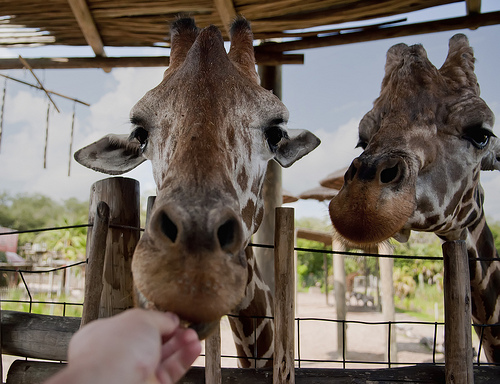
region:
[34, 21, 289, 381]
giraffe taking food from a hand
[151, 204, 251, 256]
nostrils of a giraffe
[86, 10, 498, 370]
two giraffes looking for food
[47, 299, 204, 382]
a persons hand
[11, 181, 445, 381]
fence with wooden posts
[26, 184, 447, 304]
greenery in the background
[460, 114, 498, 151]
black lashed eye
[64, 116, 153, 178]
furry little ear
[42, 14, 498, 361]
giraffes in a cage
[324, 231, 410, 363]
tall wooden posts behind the giraffes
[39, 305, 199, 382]
hand feeding a giraffe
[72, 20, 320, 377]
giraffe leaning over fence to be fed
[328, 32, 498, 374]
giraffe leaning over fence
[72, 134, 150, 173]
right ear of giraffe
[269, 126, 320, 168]
left ear of giraffe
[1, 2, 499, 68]
roof of giraffe feeding area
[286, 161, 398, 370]
stucture in the giraffe area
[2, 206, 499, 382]
fence dividing people and giraffes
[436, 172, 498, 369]
neck of giraffe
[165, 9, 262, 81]
horns on top of giraffe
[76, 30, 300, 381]
giraffe staring at camera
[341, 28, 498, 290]
giraffe staring at camera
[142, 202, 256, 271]
nostrils of tall giraffe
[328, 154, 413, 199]
nostrils of tall giraffe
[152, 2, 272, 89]
horns of tall giraffe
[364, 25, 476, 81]
horns of tall giraffe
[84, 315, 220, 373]
person petting the giraffe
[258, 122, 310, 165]
right ear of giraffe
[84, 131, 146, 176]
left ear of giraffe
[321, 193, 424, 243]
mouth of tall giraffe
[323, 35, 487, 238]
this is the giraffe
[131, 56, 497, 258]
they are two giraffes in number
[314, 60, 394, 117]
this is the sky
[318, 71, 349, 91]
the sky is blue in color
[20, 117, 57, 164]
these are the clouds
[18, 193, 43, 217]
this is a tree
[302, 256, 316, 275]
the leaves are green in color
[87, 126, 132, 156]
this is the ear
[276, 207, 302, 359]
this is a pole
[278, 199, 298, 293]
the pole is wooden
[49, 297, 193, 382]
A human hand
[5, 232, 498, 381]
A wooden fence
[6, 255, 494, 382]
Metal wire on the fence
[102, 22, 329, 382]
A giraffe eating from the hand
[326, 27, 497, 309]
A giraffe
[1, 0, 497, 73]
A wooden awning over the giraffes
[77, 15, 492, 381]
A pair of giraffes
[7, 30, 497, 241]
A clear blue sky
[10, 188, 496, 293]
A long line of trees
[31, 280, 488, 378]
A dirt pathway